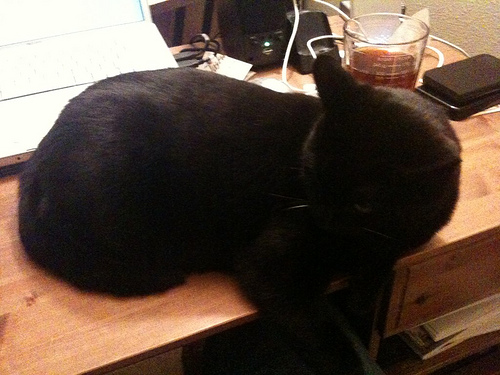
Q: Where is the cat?
A: On the desk.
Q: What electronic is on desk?
A: Laptop.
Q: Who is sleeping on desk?
A: Black cat.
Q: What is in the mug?
A: Coffee.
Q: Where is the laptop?
A: On the desk.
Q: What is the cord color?
A: White.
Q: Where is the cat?
A: Desk.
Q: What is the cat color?
A: Black.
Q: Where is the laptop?
A: Behind the cat.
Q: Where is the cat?
A: On the desk.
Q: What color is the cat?
A: Black.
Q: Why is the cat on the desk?
A: It is resting.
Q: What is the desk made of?
A: Wood.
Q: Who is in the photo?
A: Nobody.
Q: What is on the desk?
A: A cat.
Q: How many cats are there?
A: One.